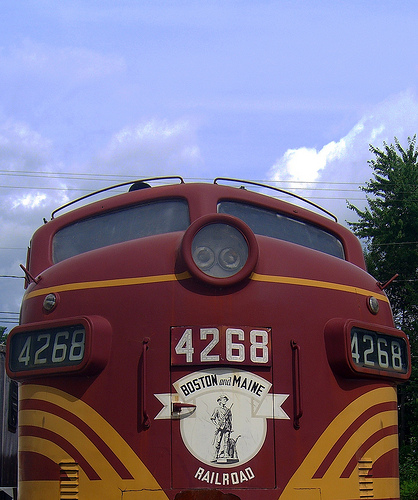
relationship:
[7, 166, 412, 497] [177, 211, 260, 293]
train has headlight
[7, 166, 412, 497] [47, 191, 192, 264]
train has window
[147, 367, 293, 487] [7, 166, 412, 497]
logo on train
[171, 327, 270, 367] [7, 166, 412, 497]
numbers are on train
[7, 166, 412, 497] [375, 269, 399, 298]
train has handle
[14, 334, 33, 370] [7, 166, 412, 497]
number 4 on train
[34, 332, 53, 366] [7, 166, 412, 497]
number 2 on train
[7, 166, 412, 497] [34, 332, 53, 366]
train has number 2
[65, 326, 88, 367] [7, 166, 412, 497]
number 8 on train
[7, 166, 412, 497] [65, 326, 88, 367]
train has number 8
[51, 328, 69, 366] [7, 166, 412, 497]
number 6 on train